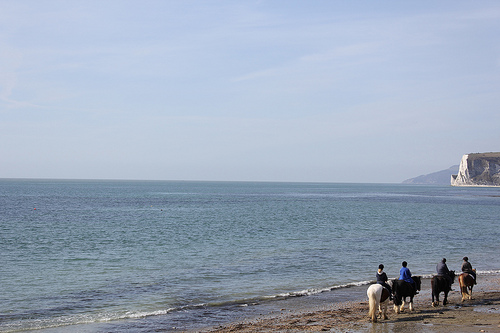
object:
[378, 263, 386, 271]
hat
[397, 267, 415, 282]
shirt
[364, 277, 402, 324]
horse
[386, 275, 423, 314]
horse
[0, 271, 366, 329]
wave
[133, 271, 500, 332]
sand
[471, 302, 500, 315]
puddle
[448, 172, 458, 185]
cliff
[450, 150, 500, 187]
mountain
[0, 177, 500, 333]
ocean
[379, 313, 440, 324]
shadow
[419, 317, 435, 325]
mark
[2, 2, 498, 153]
sky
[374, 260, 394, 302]
person